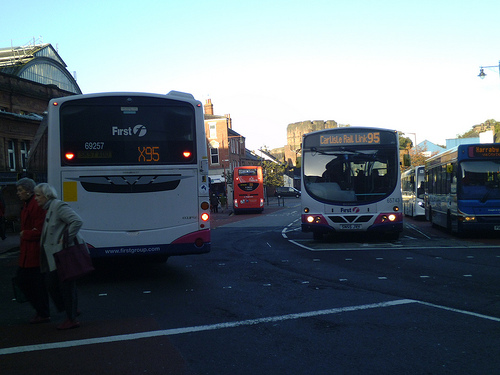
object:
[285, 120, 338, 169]
building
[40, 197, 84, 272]
coat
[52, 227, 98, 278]
bag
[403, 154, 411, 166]
mirror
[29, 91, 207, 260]
bus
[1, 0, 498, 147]
sky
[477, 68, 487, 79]
lamp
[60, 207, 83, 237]
arm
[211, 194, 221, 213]
person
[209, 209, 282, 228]
sidewalk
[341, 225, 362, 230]
license plate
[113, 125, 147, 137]
logo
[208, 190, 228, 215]
passengers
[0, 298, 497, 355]
line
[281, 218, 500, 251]
line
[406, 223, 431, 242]
line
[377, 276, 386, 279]
line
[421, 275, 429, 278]
line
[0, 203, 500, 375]
asphalt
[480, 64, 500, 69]
pole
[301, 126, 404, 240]
bus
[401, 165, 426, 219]
bus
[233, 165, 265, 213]
bus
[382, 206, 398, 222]
headlights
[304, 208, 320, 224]
headlights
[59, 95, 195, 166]
window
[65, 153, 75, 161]
light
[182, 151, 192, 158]
light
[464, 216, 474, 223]
headlight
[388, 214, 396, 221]
headlight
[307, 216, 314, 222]
headlight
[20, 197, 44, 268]
jacket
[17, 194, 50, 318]
coat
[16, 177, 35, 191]
hair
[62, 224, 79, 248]
handle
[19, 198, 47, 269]
red coat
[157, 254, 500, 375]
intersection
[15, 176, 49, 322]
elderly woman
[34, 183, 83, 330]
elderly woman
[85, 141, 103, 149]
white numbers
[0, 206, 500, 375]
road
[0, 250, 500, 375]
crosswalk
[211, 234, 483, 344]
marked area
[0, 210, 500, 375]
street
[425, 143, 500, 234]
bus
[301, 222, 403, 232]
bumper